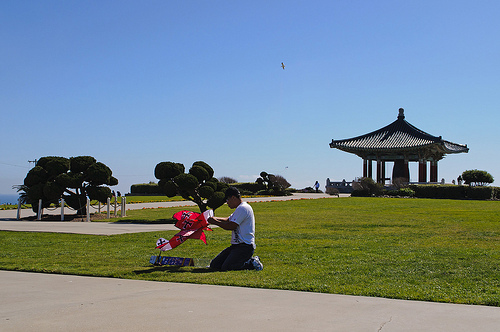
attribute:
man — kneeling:
[206, 186, 265, 272]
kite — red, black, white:
[153, 208, 215, 252]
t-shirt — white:
[227, 203, 257, 246]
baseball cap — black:
[219, 186, 241, 205]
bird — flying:
[279, 60, 287, 70]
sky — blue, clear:
[1, 0, 499, 201]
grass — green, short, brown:
[0, 199, 498, 305]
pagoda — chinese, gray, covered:
[326, 106, 470, 194]